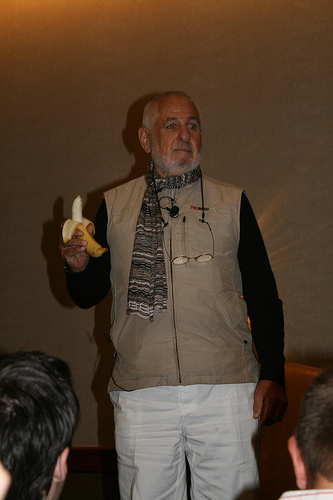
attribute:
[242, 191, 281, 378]
slleves — dark 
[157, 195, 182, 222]
microphone — black 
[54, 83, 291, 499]
man — balding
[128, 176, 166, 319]
scarf — knitted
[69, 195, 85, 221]
banana — yellow 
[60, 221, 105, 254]
peel — yellow 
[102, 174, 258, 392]
vest jacket — tan 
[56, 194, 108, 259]
banana — half peeled, peeled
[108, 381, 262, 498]
pants — white , wrinkled 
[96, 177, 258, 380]
vest — tan 